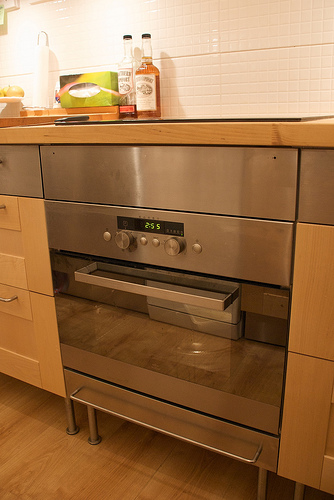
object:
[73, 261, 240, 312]
handle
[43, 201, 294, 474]
oven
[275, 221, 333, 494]
cupboards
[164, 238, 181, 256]
control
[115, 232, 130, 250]
control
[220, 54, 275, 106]
tile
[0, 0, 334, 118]
wall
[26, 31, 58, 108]
paper-towel roll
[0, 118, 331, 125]
cooktop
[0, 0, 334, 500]
kitchen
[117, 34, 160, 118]
bottles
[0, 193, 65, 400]
drawers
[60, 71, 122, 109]
box